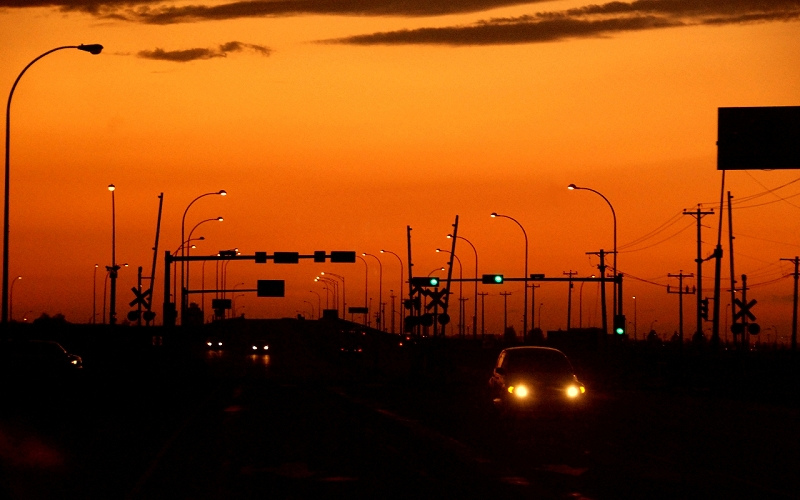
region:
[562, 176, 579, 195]
street light on pole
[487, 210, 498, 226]
street light on pole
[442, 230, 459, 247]
street light on pole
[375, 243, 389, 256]
street light on pole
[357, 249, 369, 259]
street light on pole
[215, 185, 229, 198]
street light on pole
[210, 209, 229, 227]
street light on pole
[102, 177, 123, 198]
street light on pole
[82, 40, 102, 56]
street light on pole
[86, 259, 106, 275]
street light on pole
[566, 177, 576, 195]
street light on pole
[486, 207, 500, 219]
street light on pole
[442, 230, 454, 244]
street light on pole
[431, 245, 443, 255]
street light on pole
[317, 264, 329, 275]
street light on pole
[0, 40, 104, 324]
street light is beside road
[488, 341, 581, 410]
car lights are on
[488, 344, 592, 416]
car is driving on the street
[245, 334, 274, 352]
car lights are on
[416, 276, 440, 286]
traffic light is green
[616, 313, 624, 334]
traffic light is green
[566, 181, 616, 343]
street light is beside traffic light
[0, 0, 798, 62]
clouds are in the sky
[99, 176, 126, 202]
light on the pole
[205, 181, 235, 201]
light on the pole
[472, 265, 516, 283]
light on the pole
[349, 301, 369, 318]
light on the pole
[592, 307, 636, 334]
light on the pole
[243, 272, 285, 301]
light on the pole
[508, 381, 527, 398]
The left car headlight is on.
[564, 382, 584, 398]
The right car headlight is on.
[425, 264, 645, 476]
car on the ground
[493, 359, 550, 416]
bright light on car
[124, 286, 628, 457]
many cars on the road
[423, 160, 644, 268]
lights above the ground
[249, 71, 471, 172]
orange sky above the ground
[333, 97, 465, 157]
clear sky above land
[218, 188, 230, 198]
post has a light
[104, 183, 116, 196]
post has a light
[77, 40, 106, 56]
post has a light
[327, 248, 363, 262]
post has a light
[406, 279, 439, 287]
post has a light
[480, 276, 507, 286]
post has a light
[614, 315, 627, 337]
post has a light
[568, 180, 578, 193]
post has a light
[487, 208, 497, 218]
post has a light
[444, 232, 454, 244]
post has a light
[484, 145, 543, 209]
white clouds in orange sky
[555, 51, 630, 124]
white clouds in orange sky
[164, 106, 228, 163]
white clouds in orange sky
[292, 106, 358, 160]
white clouds in orange sky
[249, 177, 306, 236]
white clouds in orange sky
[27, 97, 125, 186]
white clouds in orange sky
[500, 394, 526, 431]
the vehicles front tire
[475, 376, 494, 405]
the vehicles rear tire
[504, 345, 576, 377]
the front windshield of the vehicle